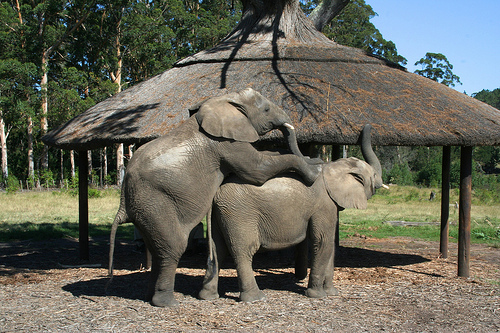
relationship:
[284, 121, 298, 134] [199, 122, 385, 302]
tusk of elephant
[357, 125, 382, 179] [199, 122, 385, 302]
trunk of elephant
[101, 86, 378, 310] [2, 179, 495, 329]
elephants in compound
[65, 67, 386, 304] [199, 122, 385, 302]
elephant mounting elephant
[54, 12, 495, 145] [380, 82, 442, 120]
roof made from natural resources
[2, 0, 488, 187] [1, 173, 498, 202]
area outside fence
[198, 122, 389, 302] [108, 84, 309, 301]
elephant mounted by elephant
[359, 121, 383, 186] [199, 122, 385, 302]
trunk of elephant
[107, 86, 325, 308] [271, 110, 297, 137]
elephant has tusks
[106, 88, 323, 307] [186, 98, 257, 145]
elephant has ears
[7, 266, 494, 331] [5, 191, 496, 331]
bark on ground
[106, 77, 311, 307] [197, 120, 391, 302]
male on back female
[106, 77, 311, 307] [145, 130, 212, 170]
male has patch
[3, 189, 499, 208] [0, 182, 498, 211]
grass near back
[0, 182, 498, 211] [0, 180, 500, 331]
back of enclosure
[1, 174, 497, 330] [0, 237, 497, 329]
ground covered with woodchips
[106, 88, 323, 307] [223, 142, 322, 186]
elephant with leg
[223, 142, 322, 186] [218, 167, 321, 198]
leg on elephant's back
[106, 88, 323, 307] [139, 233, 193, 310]
elephant standing on legs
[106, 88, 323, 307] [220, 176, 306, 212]
elephant standing in back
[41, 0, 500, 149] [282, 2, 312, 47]
roof made of straw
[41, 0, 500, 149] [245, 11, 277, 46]
roof made of straw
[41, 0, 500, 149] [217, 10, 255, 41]
roof made of straw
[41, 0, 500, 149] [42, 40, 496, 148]
roof made of straw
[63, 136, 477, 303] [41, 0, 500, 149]
poles supporting roof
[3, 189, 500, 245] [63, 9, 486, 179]
grass behind structure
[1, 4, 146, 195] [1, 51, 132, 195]
trees with trunks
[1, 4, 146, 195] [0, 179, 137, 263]
trees growing behind grasses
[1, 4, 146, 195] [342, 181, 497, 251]
trees growing behind grasses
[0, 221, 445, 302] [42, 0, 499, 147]
shadow under roof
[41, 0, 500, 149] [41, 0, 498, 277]
roof of shelter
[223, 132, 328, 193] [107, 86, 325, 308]
leg on elephant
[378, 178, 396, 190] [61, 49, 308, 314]
tusk on elephant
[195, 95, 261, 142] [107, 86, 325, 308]
ear on elephant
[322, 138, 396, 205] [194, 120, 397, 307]
elephant's head on elephant